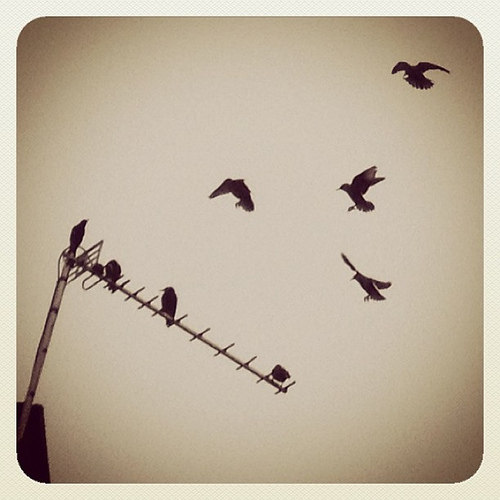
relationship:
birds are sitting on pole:
[67, 218, 292, 386] [18, 246, 79, 434]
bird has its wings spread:
[391, 58, 450, 94] [387, 57, 450, 75]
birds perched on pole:
[159, 286, 177, 328] [18, 246, 79, 434]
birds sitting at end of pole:
[159, 286, 177, 328] [18, 246, 79, 434]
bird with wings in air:
[391, 58, 450, 94] [387, 57, 450, 75]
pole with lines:
[18, 246, 79, 434] [102, 271, 293, 397]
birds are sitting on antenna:
[67, 218, 292, 386] [102, 271, 293, 397]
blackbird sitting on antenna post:
[66, 217, 89, 258] [34, 222, 297, 457]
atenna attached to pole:
[102, 271, 293, 397] [18, 247, 76, 441]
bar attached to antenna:
[18, 246, 79, 434] [102, 271, 293, 397]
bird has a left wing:
[391, 58, 450, 94] [420, 59, 453, 79]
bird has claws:
[209, 175, 257, 216] [230, 197, 242, 209]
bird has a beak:
[391, 58, 450, 94] [401, 71, 411, 84]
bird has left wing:
[391, 58, 450, 94] [418, 61, 450, 74]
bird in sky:
[209, 175, 257, 216] [16, 14, 484, 485]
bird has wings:
[209, 175, 257, 216] [206, 180, 230, 199]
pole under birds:
[18, 246, 79, 434] [67, 218, 292, 386]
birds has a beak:
[159, 286, 177, 328] [156, 284, 168, 295]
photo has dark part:
[26, 6, 488, 479] [378, 391, 488, 479]